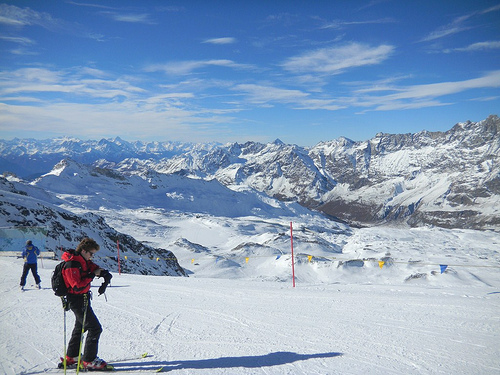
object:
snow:
[0, 119, 500, 287]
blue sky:
[0, 0, 498, 154]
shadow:
[107, 351, 345, 373]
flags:
[378, 261, 385, 270]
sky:
[1, 0, 499, 141]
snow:
[0, 256, 498, 374]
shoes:
[79, 356, 106, 369]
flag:
[439, 264, 447, 274]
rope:
[119, 253, 498, 268]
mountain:
[0, 114, 500, 276]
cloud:
[0, 0, 499, 142]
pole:
[290, 221, 296, 287]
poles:
[58, 291, 92, 371]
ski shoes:
[64, 354, 83, 366]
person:
[16, 239, 41, 290]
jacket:
[22, 244, 40, 264]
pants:
[19, 263, 41, 286]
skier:
[51, 237, 114, 371]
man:
[51, 238, 115, 372]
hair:
[75, 237, 100, 252]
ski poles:
[66, 295, 103, 362]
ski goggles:
[87, 250, 95, 257]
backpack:
[50, 261, 82, 297]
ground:
[0, 257, 499, 375]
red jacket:
[61, 248, 105, 294]